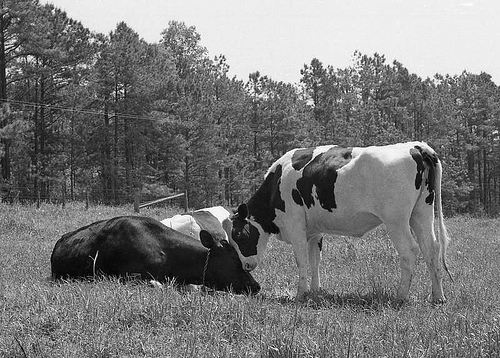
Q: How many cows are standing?
A: One.